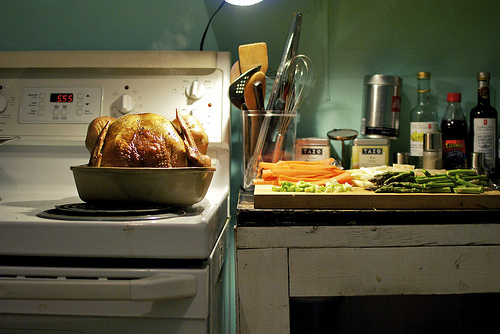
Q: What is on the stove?
A: Turkey.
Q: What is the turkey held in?
A: Baking dish.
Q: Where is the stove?
A: Left of counter.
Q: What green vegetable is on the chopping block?
A: Asparagus.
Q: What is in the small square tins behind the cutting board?
A: Spices.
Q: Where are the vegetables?
A: Cutting board.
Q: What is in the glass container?
A: Cooking utensils.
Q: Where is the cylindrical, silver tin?
A: On top of the Tazo tin.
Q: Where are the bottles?
A: On the counter.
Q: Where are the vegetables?
A: On the wooden cutting board.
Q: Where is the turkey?
A: On the white stove top oven.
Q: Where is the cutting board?
A: On a white wooden table.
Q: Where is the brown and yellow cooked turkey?
A: In a pan.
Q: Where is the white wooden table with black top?
A: Next to the oven.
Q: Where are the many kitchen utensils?
A: In a clear container.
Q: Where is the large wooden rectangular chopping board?
A: On the table.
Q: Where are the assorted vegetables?
A: On the chopping board.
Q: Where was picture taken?
A: A kitchen.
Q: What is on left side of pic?
A: A stove.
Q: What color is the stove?
A: White.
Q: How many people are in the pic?
A: None.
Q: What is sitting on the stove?
A: A cooked turkey.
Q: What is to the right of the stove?
A: A counter.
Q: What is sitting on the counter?
A: Chopped vegetables.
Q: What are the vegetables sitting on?
A: A cutting board.